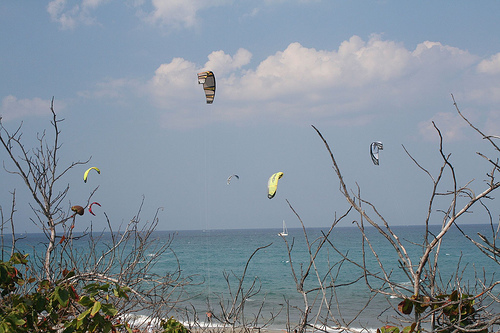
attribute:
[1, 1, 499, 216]
sky — blue, big, cloudy, huge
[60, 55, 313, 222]
kites — flying, white, blue, red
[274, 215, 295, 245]
boat — small, white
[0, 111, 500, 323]
trees — bare, leafless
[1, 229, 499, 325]
water — blue